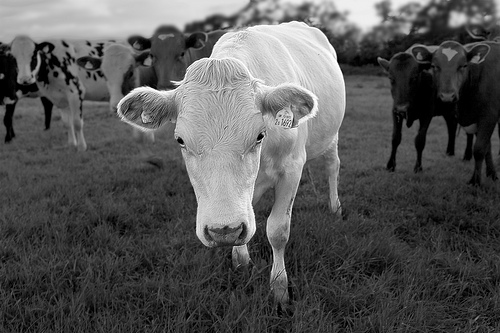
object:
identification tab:
[139, 108, 159, 124]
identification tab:
[274, 102, 294, 129]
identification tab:
[42, 44, 50, 53]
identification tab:
[132, 40, 143, 50]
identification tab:
[193, 37, 205, 48]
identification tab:
[416, 51, 424, 60]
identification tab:
[469, 52, 481, 64]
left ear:
[264, 83, 319, 130]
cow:
[111, 19, 349, 317]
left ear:
[466, 43, 490, 65]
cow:
[410, 39, 500, 188]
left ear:
[185, 31, 209, 51]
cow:
[125, 23, 235, 92]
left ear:
[35, 41, 56, 54]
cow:
[2, 33, 156, 153]